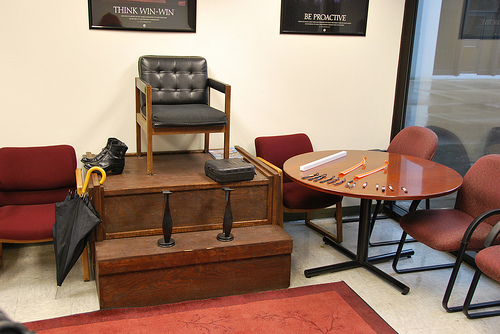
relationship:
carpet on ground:
[18, 279, 397, 333] [5, 207, 498, 331]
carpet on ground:
[12, 279, 429, 332] [5, 207, 498, 331]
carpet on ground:
[18, 279, 397, 333] [402, 294, 437, 327]